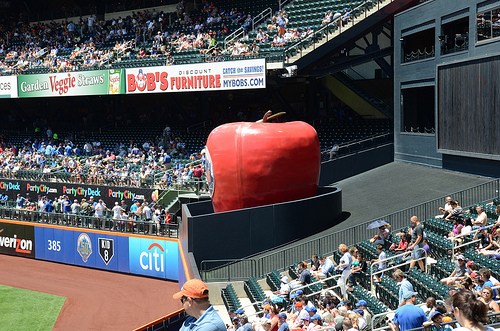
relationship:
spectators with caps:
[258, 296, 308, 321] [259, 301, 302, 309]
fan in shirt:
[172, 278, 226, 330] [180, 306, 224, 329]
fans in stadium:
[181, 187, 497, 329] [1, 2, 498, 329]